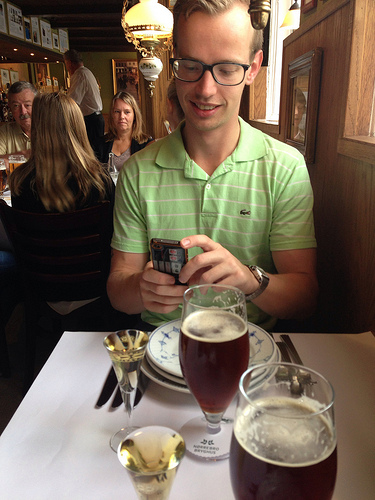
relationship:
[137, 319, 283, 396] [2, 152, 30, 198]
plate behind glass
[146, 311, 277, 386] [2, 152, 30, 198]
plate behind glass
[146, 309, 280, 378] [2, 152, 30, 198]
plate behind glass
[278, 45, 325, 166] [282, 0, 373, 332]
wooden frame on wall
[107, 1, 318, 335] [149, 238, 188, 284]
man holding cell phone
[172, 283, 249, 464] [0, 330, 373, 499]
beer glass on table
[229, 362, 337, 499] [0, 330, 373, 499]
beer glass on table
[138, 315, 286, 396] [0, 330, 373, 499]
plates on table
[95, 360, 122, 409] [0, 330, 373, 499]
knife on table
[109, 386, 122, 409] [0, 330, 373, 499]
knife on table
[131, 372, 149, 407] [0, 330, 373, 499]
knife on table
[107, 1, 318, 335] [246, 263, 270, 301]
man wearing watch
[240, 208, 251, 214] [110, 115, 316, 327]
alligator on shirt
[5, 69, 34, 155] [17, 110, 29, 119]
man has mustache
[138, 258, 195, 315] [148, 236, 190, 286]
hand holding cell phone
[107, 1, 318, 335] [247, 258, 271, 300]
man wearing watch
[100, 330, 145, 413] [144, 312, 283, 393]
cup beside plate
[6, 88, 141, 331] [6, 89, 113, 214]
woman with hair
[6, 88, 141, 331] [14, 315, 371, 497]
woman next to table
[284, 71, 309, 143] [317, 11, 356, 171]
mirror on wall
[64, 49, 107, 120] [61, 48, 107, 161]
man at bar ordering drink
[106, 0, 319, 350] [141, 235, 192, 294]
person holding phone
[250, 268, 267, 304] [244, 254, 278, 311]
watch on wrist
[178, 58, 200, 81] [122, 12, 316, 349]
eye of person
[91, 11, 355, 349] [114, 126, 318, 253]
person wearing shirt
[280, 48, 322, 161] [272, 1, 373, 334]
picture on wall